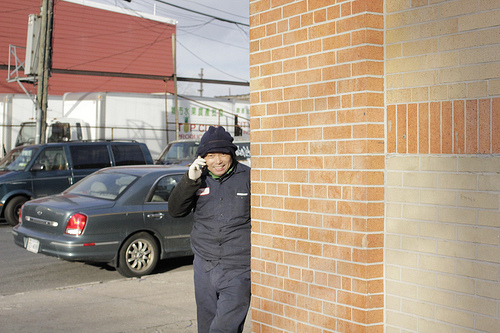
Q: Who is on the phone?
A: The man.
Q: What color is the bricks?
A: Red and brown.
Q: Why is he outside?
A: To talk on the phone.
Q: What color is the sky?
A: Blue.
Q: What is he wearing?
A: Clothes.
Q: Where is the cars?
A: Parked in the street.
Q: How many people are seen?
A: One.